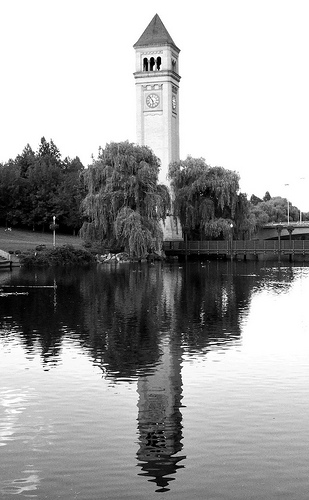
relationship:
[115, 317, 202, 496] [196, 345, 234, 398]
reflection of building in water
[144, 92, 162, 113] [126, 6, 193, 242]
clock on clock tower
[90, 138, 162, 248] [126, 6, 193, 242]
trees are surrounding clock tower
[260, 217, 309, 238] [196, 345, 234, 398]
bridge over water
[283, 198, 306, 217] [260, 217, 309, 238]
lights on bridge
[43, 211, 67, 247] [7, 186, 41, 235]
light post next to shrubs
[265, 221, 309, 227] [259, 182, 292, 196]
freeway in background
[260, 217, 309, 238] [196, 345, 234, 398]
bridge across water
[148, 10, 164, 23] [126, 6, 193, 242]
tip of clock tower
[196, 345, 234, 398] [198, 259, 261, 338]
water had tree shadows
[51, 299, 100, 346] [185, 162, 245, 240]
shadow of tree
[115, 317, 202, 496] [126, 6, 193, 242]
reflection of clock tower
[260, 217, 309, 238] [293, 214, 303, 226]
bridge for driving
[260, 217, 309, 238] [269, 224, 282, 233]
bridge for walking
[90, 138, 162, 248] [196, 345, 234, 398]
trees near water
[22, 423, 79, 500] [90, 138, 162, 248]
pond by trees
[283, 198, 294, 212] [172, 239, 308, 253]
lights on bridge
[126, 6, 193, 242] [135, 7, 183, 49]
clock tower has a roof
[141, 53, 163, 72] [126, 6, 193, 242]
pillars on clock tower